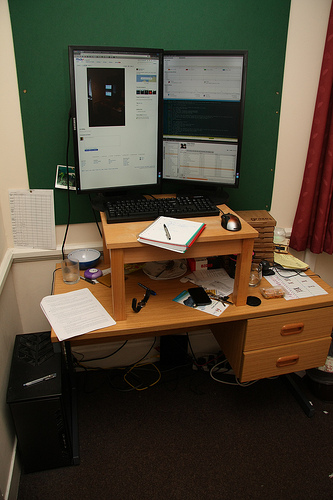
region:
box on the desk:
[244, 217, 273, 228]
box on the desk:
[251, 226, 273, 234]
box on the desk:
[255, 238, 272, 242]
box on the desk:
[254, 233, 273, 240]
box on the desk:
[253, 242, 271, 247]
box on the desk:
[252, 254, 273, 257]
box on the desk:
[255, 255, 272, 261]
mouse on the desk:
[213, 210, 245, 234]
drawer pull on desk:
[278, 322, 301, 338]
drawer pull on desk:
[273, 357, 294, 374]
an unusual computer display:
[44, 34, 296, 288]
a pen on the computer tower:
[9, 353, 82, 420]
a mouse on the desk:
[212, 211, 253, 240]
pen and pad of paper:
[132, 215, 231, 263]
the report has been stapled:
[25, 276, 117, 349]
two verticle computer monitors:
[42, 27, 263, 203]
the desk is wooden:
[131, 198, 330, 398]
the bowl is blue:
[45, 230, 119, 305]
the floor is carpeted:
[169, 375, 272, 419]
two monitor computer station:
[43, 29, 323, 396]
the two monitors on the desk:
[66, 41, 249, 192]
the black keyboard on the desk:
[103, 193, 220, 224]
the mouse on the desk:
[220, 212, 241, 232]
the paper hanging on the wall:
[7, 188, 56, 249]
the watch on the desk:
[130, 288, 149, 312]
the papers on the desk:
[37, 286, 115, 341]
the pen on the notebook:
[162, 223, 171, 240]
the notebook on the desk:
[136, 214, 205, 253]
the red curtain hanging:
[287, 35, 331, 255]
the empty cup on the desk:
[60, 258, 79, 284]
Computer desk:
[43, 191, 331, 385]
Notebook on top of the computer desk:
[137, 214, 206, 253]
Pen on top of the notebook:
[161, 222, 173, 241]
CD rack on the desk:
[65, 248, 102, 270]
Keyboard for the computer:
[100, 195, 222, 221]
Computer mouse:
[218, 209, 241, 234]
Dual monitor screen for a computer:
[67, 44, 249, 195]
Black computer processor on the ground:
[6, 330, 80, 472]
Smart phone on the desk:
[185, 282, 211, 307]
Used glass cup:
[58, 257, 81, 285]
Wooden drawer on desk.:
[246, 321, 324, 339]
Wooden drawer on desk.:
[238, 348, 324, 377]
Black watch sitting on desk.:
[132, 286, 157, 314]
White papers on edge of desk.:
[42, 277, 114, 345]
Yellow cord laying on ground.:
[122, 358, 164, 401]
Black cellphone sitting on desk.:
[190, 282, 213, 311]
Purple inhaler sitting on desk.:
[84, 269, 102, 279]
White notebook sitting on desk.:
[144, 216, 199, 265]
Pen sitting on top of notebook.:
[158, 224, 177, 246]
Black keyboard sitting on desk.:
[102, 198, 219, 215]